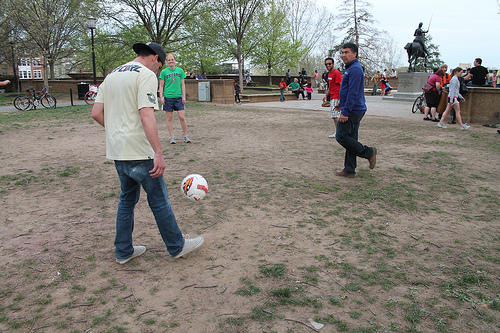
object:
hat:
[131, 40, 168, 65]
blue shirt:
[336, 58, 368, 118]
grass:
[235, 157, 399, 248]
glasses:
[325, 62, 334, 66]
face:
[325, 58, 334, 71]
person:
[157, 52, 193, 144]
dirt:
[1, 98, 498, 329]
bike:
[411, 85, 429, 114]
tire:
[411, 96, 424, 113]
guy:
[91, 41, 207, 265]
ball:
[179, 172, 209, 203]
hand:
[148, 152, 165, 178]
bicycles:
[12, 85, 57, 112]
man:
[321, 56, 346, 139]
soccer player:
[158, 48, 193, 145]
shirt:
[159, 66, 187, 99]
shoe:
[168, 235, 209, 259]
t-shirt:
[324, 68, 341, 98]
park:
[0, 66, 416, 330]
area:
[30, 111, 426, 329]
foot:
[171, 233, 206, 260]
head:
[132, 41, 167, 75]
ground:
[12, 115, 392, 322]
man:
[331, 42, 378, 178]